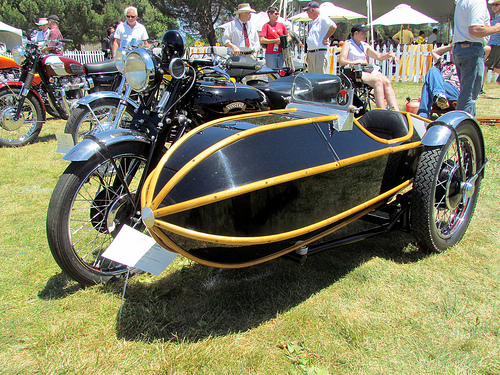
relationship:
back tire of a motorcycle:
[408, 116, 495, 252] [0, 40, 121, 148]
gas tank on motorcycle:
[215, 86, 255, 122] [75, 39, 457, 266]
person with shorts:
[338, 24, 399, 113] [335, 15, 428, 147]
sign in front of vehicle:
[96, 224, 186, 285] [37, 27, 495, 297]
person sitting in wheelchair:
[336, 20, 396, 99] [340, 94, 372, 106]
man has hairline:
[111, 6, 149, 59] [125, 3, 140, 10]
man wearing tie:
[222, 3, 262, 66] [235, 20, 252, 44]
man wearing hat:
[222, 3, 262, 66] [228, 3, 253, 13]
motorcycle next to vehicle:
[43, 78, 441, 286] [167, 134, 365, 190]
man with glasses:
[106, 0, 180, 74] [114, 6, 141, 19]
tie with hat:
[232, 19, 267, 63] [213, 0, 262, 10]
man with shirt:
[305, 0, 337, 75] [251, 22, 297, 49]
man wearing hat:
[222, 3, 262, 66] [225, 4, 258, 14]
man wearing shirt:
[222, 3, 262, 66] [221, 12, 260, 49]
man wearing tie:
[226, 6, 268, 65] [241, 26, 254, 52]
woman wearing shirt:
[339, 21, 409, 110] [336, 35, 385, 70]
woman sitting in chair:
[338, 24, 400, 112] [335, 56, 373, 106]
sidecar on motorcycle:
[143, 109, 421, 277] [44, 44, 479, 280]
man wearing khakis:
[295, 0, 335, 86] [304, 48, 328, 77]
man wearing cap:
[295, 0, 335, 86] [296, 3, 322, 13]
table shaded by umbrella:
[388, 51, 432, 74] [364, 1, 439, 36]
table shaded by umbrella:
[304, 41, 349, 62] [288, 3, 368, 23]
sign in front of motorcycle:
[101, 223, 178, 277] [52, 69, 484, 286]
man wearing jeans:
[449, 2, 483, 114] [451, 46, 484, 109]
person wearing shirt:
[260, 5, 293, 74] [259, 22, 288, 55]